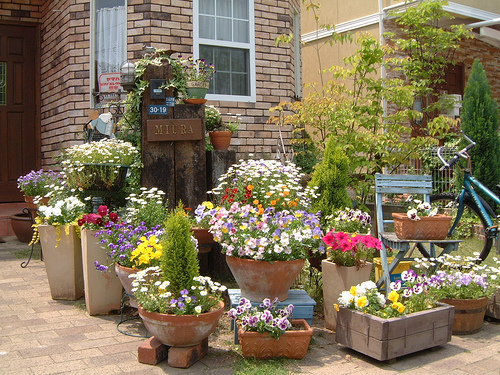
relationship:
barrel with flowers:
[427, 295, 488, 334] [417, 252, 497, 301]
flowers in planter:
[406, 197, 440, 224] [389, 211, 452, 240]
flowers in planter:
[18, 168, 65, 198] [24, 194, 47, 224]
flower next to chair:
[372, 237, 383, 253] [368, 165, 462, 289]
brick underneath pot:
[132, 331, 171, 370] [132, 290, 231, 347]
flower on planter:
[388, 302, 405, 316] [337, 283, 456, 360]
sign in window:
[97, 70, 126, 95] [85, 1, 132, 102]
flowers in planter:
[96, 219, 163, 268] [111, 262, 160, 308]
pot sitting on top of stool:
[222, 250, 306, 300] [222, 284, 317, 344]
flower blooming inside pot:
[191, 301, 202, 313] [134, 292, 225, 346]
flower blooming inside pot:
[261, 295, 271, 310] [234, 317, 313, 358]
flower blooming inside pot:
[256, 234, 270, 246] [222, 250, 306, 300]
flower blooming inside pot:
[337, 239, 353, 251] [319, 253, 373, 330]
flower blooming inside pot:
[405, 206, 419, 220] [391, 208, 451, 238]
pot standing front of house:
[134, 292, 225, 346] [1, 1, 308, 236]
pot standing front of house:
[234, 317, 313, 358] [1, 1, 308, 236]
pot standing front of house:
[222, 250, 306, 300] [1, 1, 308, 236]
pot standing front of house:
[319, 253, 373, 330] [1, 1, 308, 236]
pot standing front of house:
[391, 208, 451, 238] [1, 1, 308, 236]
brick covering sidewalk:
[15, 309, 60, 321] [1, 234, 484, 372]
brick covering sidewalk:
[69, 335, 120, 351] [1, 234, 484, 372]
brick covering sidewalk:
[29, 355, 91, 373] [1, 234, 484, 372]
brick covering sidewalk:
[53, 321, 103, 335] [1, 234, 484, 372]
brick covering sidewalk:
[16, 340, 74, 359] [1, 234, 484, 372]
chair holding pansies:
[368, 165, 462, 289] [404, 197, 440, 219]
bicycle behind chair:
[413, 130, 499, 274] [373, 171, 462, 290]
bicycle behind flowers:
[413, 130, 499, 274] [407, 200, 440, 220]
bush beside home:
[307, 0, 469, 213] [300, 0, 499, 198]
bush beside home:
[307, 0, 469, 213] [0, 0, 303, 239]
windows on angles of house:
[80, 0, 280, 123] [7, 4, 321, 216]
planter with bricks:
[122, 199, 238, 342] [130, 330, 217, 370]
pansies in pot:
[401, 195, 438, 222] [389, 208, 455, 233]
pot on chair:
[389, 208, 455, 233] [362, 160, 457, 281]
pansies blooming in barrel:
[429, 265, 491, 300] [441, 292, 495, 353]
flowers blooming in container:
[328, 275, 457, 318] [327, 305, 465, 363]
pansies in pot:
[203, 200, 339, 252] [220, 250, 319, 309]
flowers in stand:
[15, 161, 70, 219] [7, 194, 43, 242]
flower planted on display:
[194, 58, 201, 73] [139, 60, 209, 213]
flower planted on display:
[175, 53, 184, 63] [139, 60, 209, 213]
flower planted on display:
[206, 61, 215, 71] [139, 60, 209, 213]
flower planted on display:
[197, 65, 204, 75] [139, 60, 209, 213]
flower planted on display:
[162, 47, 176, 61] [139, 60, 209, 213]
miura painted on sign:
[153, 120, 193, 135] [142, 115, 203, 142]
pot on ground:
[241, 322, 319, 365] [175, 344, 360, 369]